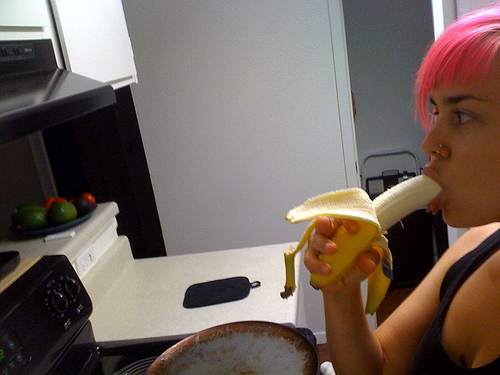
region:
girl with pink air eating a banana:
[282, 10, 499, 373]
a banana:
[280, 171, 440, 312]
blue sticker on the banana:
[381, 256, 392, 278]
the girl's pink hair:
[413, 3, 497, 135]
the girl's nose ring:
[433, 140, 442, 156]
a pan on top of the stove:
[148, 320, 318, 374]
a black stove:
[0, 255, 316, 373]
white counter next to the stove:
[17, 196, 301, 328]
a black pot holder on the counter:
[187, 274, 263, 306]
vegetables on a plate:
[12, 191, 97, 234]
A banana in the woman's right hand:
[282, 172, 439, 313]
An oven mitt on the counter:
[181, 274, 259, 308]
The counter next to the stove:
[91, 242, 303, 344]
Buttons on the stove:
[51, 277, 81, 310]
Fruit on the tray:
[10, 194, 93, 237]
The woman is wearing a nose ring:
[436, 142, 443, 154]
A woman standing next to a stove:
[303, 7, 498, 374]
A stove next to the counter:
[1, 255, 296, 373]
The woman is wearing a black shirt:
[420, 229, 498, 374]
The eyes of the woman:
[431, 109, 472, 124]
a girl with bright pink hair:
[302, 9, 496, 374]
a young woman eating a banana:
[302, 5, 497, 372]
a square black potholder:
[183, 275, 259, 307]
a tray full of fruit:
[4, 192, 96, 234]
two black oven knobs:
[47, 275, 82, 315]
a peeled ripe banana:
[281, 170, 441, 314]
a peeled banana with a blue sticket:
[281, 173, 443, 315]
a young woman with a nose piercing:
[283, 10, 498, 372]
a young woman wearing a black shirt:
[280, 10, 498, 374]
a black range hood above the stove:
[0, 39, 115, 144]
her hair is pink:
[398, 16, 480, 101]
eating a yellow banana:
[332, 165, 454, 245]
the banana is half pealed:
[285, 177, 416, 299]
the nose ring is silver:
[427, 127, 454, 154]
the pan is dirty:
[148, 309, 306, 372]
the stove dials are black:
[27, 259, 123, 332]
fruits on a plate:
[11, 177, 100, 257]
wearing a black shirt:
[398, 256, 488, 372]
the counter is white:
[79, 238, 309, 350]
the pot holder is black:
[148, 265, 260, 315]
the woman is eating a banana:
[283, 124, 495, 211]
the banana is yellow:
[292, 201, 485, 353]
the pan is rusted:
[190, 296, 267, 361]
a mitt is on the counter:
[166, 256, 305, 346]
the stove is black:
[21, 263, 110, 330]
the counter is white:
[112, 247, 159, 314]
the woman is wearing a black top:
[390, 287, 443, 347]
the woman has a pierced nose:
[428, 134, 473, 168]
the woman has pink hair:
[424, 30, 484, 77]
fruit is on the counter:
[28, 191, 210, 334]